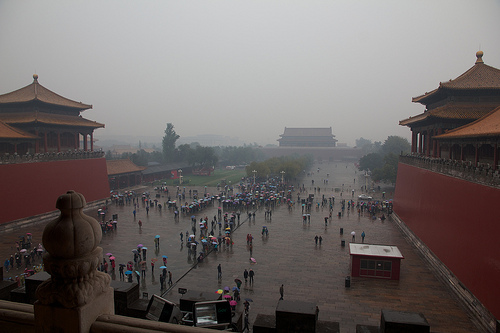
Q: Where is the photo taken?
A: Above the square.